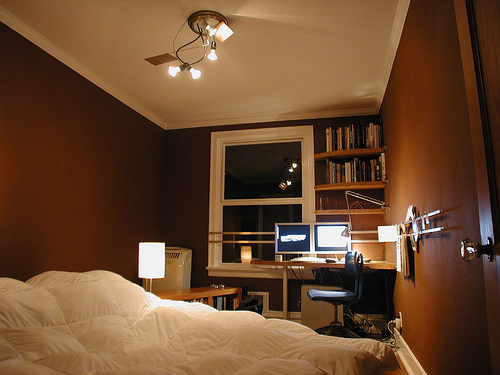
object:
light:
[278, 157, 300, 191]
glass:
[221, 140, 305, 264]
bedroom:
[0, 0, 499, 375]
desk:
[206, 260, 396, 325]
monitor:
[277, 223, 311, 252]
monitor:
[315, 224, 349, 251]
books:
[326, 122, 387, 183]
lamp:
[138, 241, 165, 292]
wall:
[0, 0, 499, 375]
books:
[326, 153, 386, 186]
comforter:
[1, 270, 398, 375]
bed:
[0, 269, 401, 375]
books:
[326, 123, 382, 152]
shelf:
[314, 184, 385, 215]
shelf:
[311, 153, 391, 191]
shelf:
[315, 123, 387, 155]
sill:
[206, 263, 316, 279]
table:
[156, 287, 243, 311]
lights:
[145, 10, 235, 80]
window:
[206, 125, 312, 267]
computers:
[274, 221, 352, 254]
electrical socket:
[392, 312, 402, 330]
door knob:
[459, 237, 493, 263]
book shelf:
[315, 117, 391, 215]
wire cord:
[384, 320, 395, 344]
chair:
[306, 251, 364, 339]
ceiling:
[0, 0, 413, 133]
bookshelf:
[315, 147, 385, 161]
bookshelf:
[315, 181, 386, 191]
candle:
[240, 246, 252, 264]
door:
[385, 0, 495, 375]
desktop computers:
[274, 222, 352, 262]